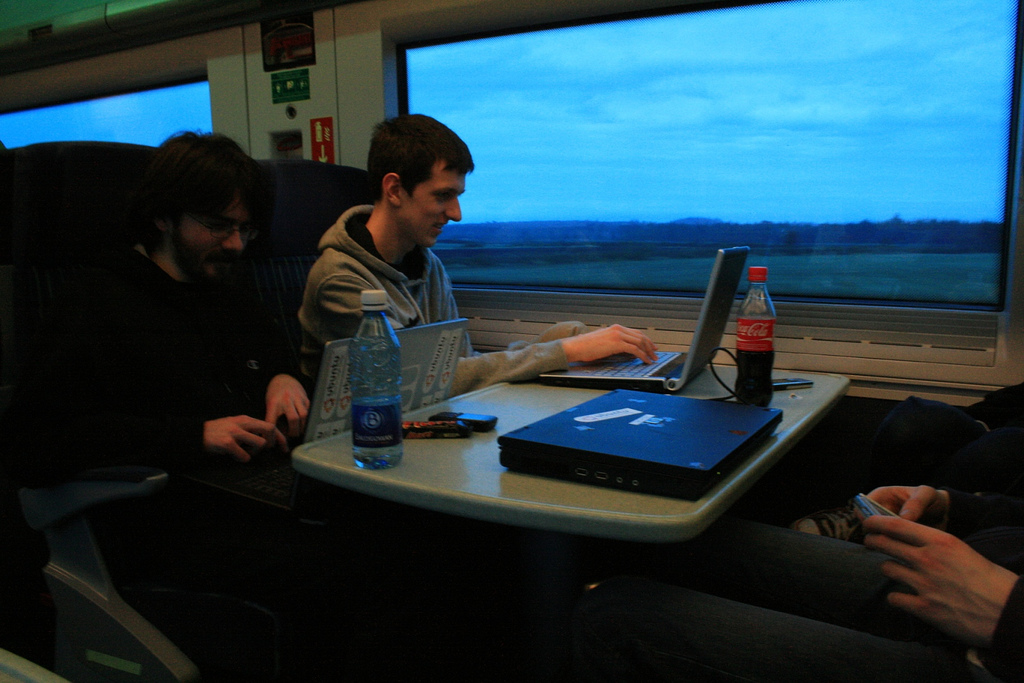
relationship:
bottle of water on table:
[330, 274, 404, 542] [296, 336, 809, 583]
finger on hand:
[879, 516, 946, 540] [849, 505, 953, 683]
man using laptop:
[0, 131, 309, 683] [240, 293, 446, 473]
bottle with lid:
[735, 266, 773, 407] [724, 257, 783, 288]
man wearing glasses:
[0, 131, 309, 683] [140, 179, 285, 266]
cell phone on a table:
[374, 399, 504, 436] [281, 332, 964, 628]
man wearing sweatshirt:
[301, 115, 659, 397] [285, 192, 590, 402]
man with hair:
[0, 131, 309, 683] [97, 120, 279, 309]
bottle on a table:
[351, 290, 403, 470] [257, 332, 873, 670]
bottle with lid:
[706, 259, 787, 424] [724, 257, 783, 288]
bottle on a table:
[735, 266, 773, 407] [257, 332, 873, 670]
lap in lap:
[165, 318, 469, 528] [82, 414, 385, 536]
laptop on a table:
[510, 246, 750, 393] [292, 356, 856, 678]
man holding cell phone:
[569, 483, 1024, 680] [849, 479, 914, 564]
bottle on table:
[735, 266, 773, 407] [218, 337, 854, 642]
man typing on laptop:
[0, 131, 309, 683] [220, 298, 478, 523]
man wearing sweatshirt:
[0, 131, 309, 683] [0, 250, 325, 575]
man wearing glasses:
[0, 108, 417, 657] [147, 170, 281, 257]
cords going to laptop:
[681, 347, 805, 419] [478, 216, 885, 517]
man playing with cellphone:
[633, 375, 988, 672] [838, 472, 975, 565]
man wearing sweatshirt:
[301, 115, 659, 397] [277, 202, 580, 393]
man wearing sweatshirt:
[281, 108, 662, 424] [266, 196, 571, 406]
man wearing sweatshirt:
[301, 115, 659, 397] [248, 168, 570, 406]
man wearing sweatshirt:
[281, 108, 662, 424] [285, 192, 590, 402]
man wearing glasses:
[0, 131, 309, 683] [199, 216, 264, 243]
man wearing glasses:
[0, 131, 309, 683] [176, 212, 259, 238]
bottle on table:
[735, 266, 773, 407] [297, 352, 849, 543]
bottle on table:
[351, 290, 403, 470] [297, 352, 849, 543]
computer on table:
[495, 387, 785, 496] [297, 352, 849, 543]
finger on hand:
[863, 533, 920, 566] [863, 514, 1011, 636]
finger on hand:
[882, 555, 932, 590] [865, 514, 1017, 659]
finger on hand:
[876, 585, 929, 616] [865, 514, 1017, 659]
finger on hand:
[904, 486, 924, 525] [848, 482, 955, 524]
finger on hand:
[865, 486, 902, 500] [860, 480, 958, 526]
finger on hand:
[230, 423, 269, 452] [197, 413, 295, 457]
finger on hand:
[262, 404, 276, 426] [268, 371, 310, 434]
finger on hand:
[614, 339, 653, 365] [560, 322, 658, 361]